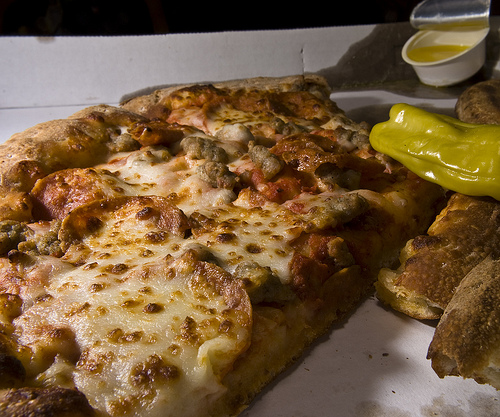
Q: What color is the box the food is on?
A: The box is white.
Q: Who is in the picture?
A: Nobody is in the picture.